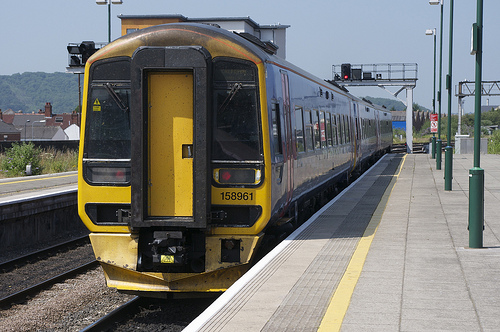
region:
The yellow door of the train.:
[147, 73, 194, 213]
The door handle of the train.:
[182, 147, 192, 158]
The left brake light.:
[109, 166, 127, 183]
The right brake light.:
[224, 170, 230, 183]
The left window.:
[88, 83, 130, 164]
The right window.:
[206, 85, 258, 160]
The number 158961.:
[217, 190, 260, 206]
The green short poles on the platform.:
[428, 108, 488, 251]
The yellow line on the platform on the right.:
[329, 140, 416, 330]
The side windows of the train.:
[272, 106, 397, 152]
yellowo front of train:
[67, 41, 244, 285]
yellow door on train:
[134, 51, 221, 216]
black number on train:
[200, 191, 246, 204]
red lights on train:
[88, 164, 247, 202]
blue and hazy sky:
[4, 22, 55, 53]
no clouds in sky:
[299, 2, 370, 46]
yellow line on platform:
[313, 140, 448, 322]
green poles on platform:
[433, 21, 479, 275]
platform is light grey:
[367, 169, 477, 329]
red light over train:
[335, 58, 357, 93]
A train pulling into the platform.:
[56, 30, 420, 310]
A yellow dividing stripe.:
[326, 281, 351, 315]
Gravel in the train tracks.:
[36, 293, 86, 316]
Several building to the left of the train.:
[13, 105, 80, 138]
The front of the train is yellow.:
[68, 29, 290, 317]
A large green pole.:
[463, 8, 485, 249]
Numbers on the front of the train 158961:
[216, 186, 259, 209]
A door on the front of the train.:
[138, 65, 203, 219]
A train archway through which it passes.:
[327, 60, 422, 160]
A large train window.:
[78, 73, 131, 198]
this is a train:
[63, 16, 285, 233]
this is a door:
[142, 72, 197, 215]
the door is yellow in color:
[160, 86, 176, 126]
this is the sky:
[311, 8, 381, 49]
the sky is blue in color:
[340, 4, 389, 49]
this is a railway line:
[19, 272, 72, 330]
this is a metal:
[88, 295, 150, 330]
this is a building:
[19, 91, 63, 138]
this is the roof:
[33, 122, 55, 134]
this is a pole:
[466, 48, 485, 238]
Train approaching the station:
[71, 35, 281, 310]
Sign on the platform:
[427, 108, 444, 140]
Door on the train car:
[143, 68, 200, 225]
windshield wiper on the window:
[211, 72, 243, 117]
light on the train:
[212, 166, 244, 182]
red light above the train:
[340, 63, 355, 87]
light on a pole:
[418, 25, 448, 41]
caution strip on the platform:
[337, 145, 439, 330]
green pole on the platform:
[442, 51, 463, 186]